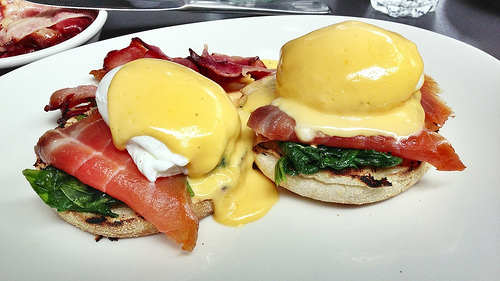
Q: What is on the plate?
A: Strips of bacon.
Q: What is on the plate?
A: Food.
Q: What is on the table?
A: White plates.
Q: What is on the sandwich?
A: Yellow sauce.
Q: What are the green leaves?
A: Spinach.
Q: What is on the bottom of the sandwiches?
A: A bun.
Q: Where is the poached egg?
A: On top of the meat.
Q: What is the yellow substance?
A: Sauce.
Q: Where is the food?
A: On the plate.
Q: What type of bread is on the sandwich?
A: English muffin.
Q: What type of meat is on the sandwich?
A: Fish.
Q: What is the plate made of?
A: Porcelain.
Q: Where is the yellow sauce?
A: On the egg whites.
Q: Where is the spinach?
A: In muffin.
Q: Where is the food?
A: On plate.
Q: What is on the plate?
A: Muffin.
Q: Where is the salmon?
A: On muffin.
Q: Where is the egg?
A: On top.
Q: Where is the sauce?
A: On muffin.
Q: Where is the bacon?
A: On plate.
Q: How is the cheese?
A: Dripping.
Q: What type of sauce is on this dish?
A: Hollandaise.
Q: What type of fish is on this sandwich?
A: Salmon.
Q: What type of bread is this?
A: English Muffin.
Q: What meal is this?
A: Breakfast.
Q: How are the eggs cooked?
A: Poached.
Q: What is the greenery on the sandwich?
A: Lettuce.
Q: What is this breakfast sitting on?
A: A white plate.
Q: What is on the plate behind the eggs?
A: Bacon.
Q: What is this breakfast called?
A: Eggs Benedict.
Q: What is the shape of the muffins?
A: Round.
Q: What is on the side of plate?
A: Bacon.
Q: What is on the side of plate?
A: Oval.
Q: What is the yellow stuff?
A: Sauce.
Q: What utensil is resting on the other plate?
A: A knife.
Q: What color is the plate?
A: White.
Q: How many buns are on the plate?
A: Two.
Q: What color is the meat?
A: Red.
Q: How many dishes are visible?
A: Two.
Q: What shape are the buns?
A: Round.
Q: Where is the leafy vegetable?
A: On the buns.